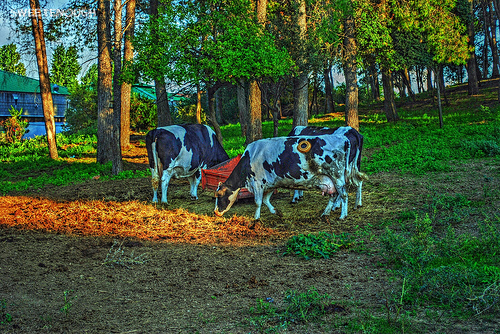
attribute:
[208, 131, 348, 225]
cow — black, white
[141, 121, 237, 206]
cow — white, grazing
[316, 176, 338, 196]
udder — white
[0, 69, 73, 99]
roof — green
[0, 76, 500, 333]
ground — bare, dark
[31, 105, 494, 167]
grass — thick, brown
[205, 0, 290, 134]
tree — treen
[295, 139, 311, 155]
object — brown, golden, circular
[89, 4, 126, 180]
tree trunk — tall, brown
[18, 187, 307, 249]
grass — golden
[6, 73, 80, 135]
building — green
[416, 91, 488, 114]
patch — brown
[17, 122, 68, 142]
wall — cement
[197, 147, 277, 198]
trough — red